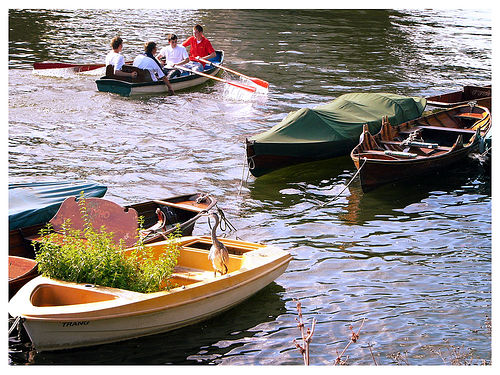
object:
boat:
[8, 176, 109, 244]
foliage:
[31, 189, 187, 294]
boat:
[8, 190, 217, 298]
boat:
[350, 100, 493, 193]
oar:
[173, 63, 256, 93]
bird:
[201, 211, 230, 277]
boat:
[7, 235, 294, 352]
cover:
[248, 92, 427, 157]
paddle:
[199, 58, 271, 89]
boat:
[426, 84, 491, 112]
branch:
[290, 297, 318, 365]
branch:
[333, 317, 366, 365]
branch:
[364, 340, 380, 365]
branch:
[384, 345, 411, 364]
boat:
[93, 48, 225, 97]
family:
[106, 24, 217, 97]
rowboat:
[32, 48, 270, 97]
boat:
[244, 92, 426, 177]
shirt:
[126, 52, 166, 83]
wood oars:
[32, 62, 107, 71]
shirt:
[181, 34, 216, 67]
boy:
[177, 24, 217, 76]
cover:
[9, 178, 108, 232]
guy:
[153, 32, 190, 75]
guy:
[106, 36, 139, 79]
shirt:
[157, 44, 190, 74]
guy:
[131, 41, 177, 96]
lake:
[9, 9, 490, 366]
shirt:
[104, 51, 126, 75]